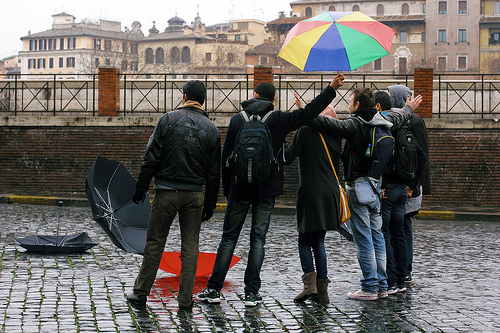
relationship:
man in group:
[122, 80, 223, 310] [122, 75, 434, 314]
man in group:
[198, 73, 346, 312] [122, 75, 434, 314]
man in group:
[293, 88, 392, 304] [122, 75, 434, 314]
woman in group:
[284, 100, 346, 305] [122, 75, 434, 314]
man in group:
[387, 82, 428, 285] [122, 75, 434, 314]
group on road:
[122, 75, 434, 314] [0, 203, 499, 332]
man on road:
[122, 80, 223, 310] [0, 203, 499, 332]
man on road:
[198, 73, 346, 312] [0, 203, 499, 332]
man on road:
[293, 88, 392, 304] [0, 203, 499, 332]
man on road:
[387, 82, 428, 285] [0, 203, 499, 332]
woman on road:
[284, 100, 346, 305] [0, 203, 499, 332]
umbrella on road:
[13, 198, 101, 257] [0, 203, 499, 332]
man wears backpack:
[198, 73, 346, 312] [226, 104, 278, 191]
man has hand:
[198, 73, 346, 312] [326, 70, 348, 90]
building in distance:
[19, 11, 145, 82] [1, 0, 498, 87]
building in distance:
[136, 5, 211, 73] [1, 0, 498, 87]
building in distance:
[288, 0, 499, 79] [1, 0, 498, 87]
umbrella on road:
[274, 7, 399, 74] [0, 203, 499, 332]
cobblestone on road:
[73, 276, 90, 288] [0, 203, 499, 332]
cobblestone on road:
[326, 307, 344, 318] [0, 203, 499, 332]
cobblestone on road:
[3, 301, 25, 312] [0, 203, 499, 332]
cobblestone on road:
[230, 319, 246, 328] [0, 203, 499, 332]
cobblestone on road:
[57, 301, 76, 312] [0, 203, 499, 332]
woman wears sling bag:
[284, 100, 346, 305] [317, 129, 352, 222]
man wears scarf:
[122, 80, 223, 310] [176, 99, 204, 112]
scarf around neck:
[176, 99, 204, 112] [187, 100, 202, 115]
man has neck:
[122, 80, 223, 310] [187, 100, 202, 115]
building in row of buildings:
[19, 11, 145, 82] [19, 0, 499, 80]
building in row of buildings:
[136, 5, 211, 73] [19, 0, 499, 80]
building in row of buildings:
[288, 0, 499, 79] [19, 0, 499, 80]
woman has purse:
[284, 100, 346, 305] [317, 129, 352, 222]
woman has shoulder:
[284, 100, 346, 305] [298, 119, 322, 139]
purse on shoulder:
[317, 129, 352, 222] [298, 119, 322, 139]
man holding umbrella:
[198, 73, 346, 312] [274, 7, 399, 74]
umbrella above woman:
[274, 7, 399, 74] [284, 100, 346, 305]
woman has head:
[284, 100, 346, 305] [319, 104, 339, 124]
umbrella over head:
[274, 7, 399, 74] [319, 104, 339, 124]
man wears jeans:
[198, 73, 346, 312] [205, 180, 279, 297]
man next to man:
[122, 80, 223, 310] [198, 73, 346, 312]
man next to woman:
[198, 73, 346, 312] [284, 100, 346, 305]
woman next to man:
[284, 100, 346, 305] [293, 88, 392, 304]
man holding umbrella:
[122, 80, 223, 310] [84, 152, 156, 258]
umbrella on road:
[152, 251, 242, 278] [0, 203, 499, 332]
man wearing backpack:
[198, 73, 346, 312] [226, 104, 278, 191]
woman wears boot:
[284, 100, 346, 305] [291, 271, 319, 305]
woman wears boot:
[284, 100, 346, 305] [309, 276, 333, 305]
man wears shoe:
[198, 73, 346, 312] [242, 290, 263, 308]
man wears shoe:
[198, 73, 346, 312] [195, 288, 223, 306]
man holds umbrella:
[122, 80, 223, 310] [84, 152, 156, 258]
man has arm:
[293, 88, 392, 304] [384, 95, 424, 129]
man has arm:
[293, 88, 392, 304] [291, 92, 355, 139]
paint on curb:
[416, 209, 456, 221] [2, 193, 499, 222]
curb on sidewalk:
[2, 193, 499, 222] [0, 186, 498, 224]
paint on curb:
[214, 203, 229, 212] [2, 193, 499, 222]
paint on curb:
[9, 194, 60, 206] [2, 193, 499, 222]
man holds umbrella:
[198, 73, 346, 312] [274, 7, 399, 74]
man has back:
[198, 73, 346, 312] [229, 108, 285, 201]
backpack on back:
[226, 104, 278, 191] [229, 108, 285, 201]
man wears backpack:
[293, 88, 392, 304] [349, 122, 396, 188]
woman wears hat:
[284, 100, 346, 305] [321, 104, 337, 122]